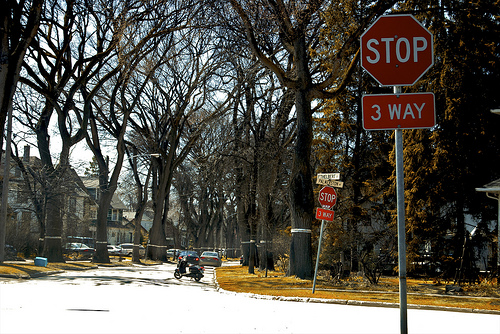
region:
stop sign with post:
[361, 6, 435, 331]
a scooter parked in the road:
[170, 256, 208, 281]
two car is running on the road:
[179, 244, 227, 265]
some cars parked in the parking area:
[63, 223, 145, 259]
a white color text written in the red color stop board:
[368, 15, 437, 84]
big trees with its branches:
[218, 13, 348, 240]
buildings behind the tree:
[18, 158, 138, 233]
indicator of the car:
[208, 253, 220, 263]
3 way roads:
[38, 280, 417, 332]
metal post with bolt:
[361, 16, 446, 332]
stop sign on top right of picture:
[356, 23, 442, 89]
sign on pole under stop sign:
[363, 86, 440, 133]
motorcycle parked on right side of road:
[171, 260, 206, 285]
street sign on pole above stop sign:
[310, 168, 348, 190]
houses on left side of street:
[9, 148, 236, 254]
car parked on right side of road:
[195, 251, 225, 267]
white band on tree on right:
[284, 224, 313, 238]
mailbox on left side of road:
[119, 243, 131, 268]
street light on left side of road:
[111, 147, 166, 174]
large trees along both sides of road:
[9, 0, 356, 282]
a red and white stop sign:
[354, 12, 442, 86]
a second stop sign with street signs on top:
[293, 163, 343, 304]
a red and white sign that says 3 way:
[353, 91, 441, 136]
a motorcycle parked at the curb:
[162, 243, 219, 288]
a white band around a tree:
[284, 216, 320, 243]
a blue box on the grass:
[26, 248, 56, 275]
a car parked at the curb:
[198, 245, 228, 275]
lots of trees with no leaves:
[24, 13, 279, 268]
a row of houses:
[8, 150, 221, 255]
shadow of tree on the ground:
[43, 261, 185, 308]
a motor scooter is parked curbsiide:
[171, 250, 208, 287]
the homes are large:
[0, 143, 246, 261]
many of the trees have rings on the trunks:
[26, 223, 318, 253]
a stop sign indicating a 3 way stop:
[353, 10, 448, 332]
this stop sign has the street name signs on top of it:
[310, 164, 344, 296]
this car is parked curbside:
[197, 245, 222, 268]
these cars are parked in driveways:
[56, 234, 182, 263]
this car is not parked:
[173, 247, 201, 269]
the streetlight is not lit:
[93, 150, 165, 180]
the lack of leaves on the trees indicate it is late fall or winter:
[1, 0, 356, 280]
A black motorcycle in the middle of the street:
[172, 254, 207, 282]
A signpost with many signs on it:
[298, 166, 353, 302]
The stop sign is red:
[357, 13, 437, 87]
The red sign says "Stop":
[362, 32, 429, 76]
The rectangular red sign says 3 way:
[358, 87, 438, 132]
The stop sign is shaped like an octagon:
[357, 11, 439, 91]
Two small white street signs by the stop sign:
[312, 168, 347, 188]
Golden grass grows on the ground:
[228, 272, 304, 297]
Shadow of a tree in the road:
[44, 268, 162, 293]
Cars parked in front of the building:
[71, 234, 138, 262]